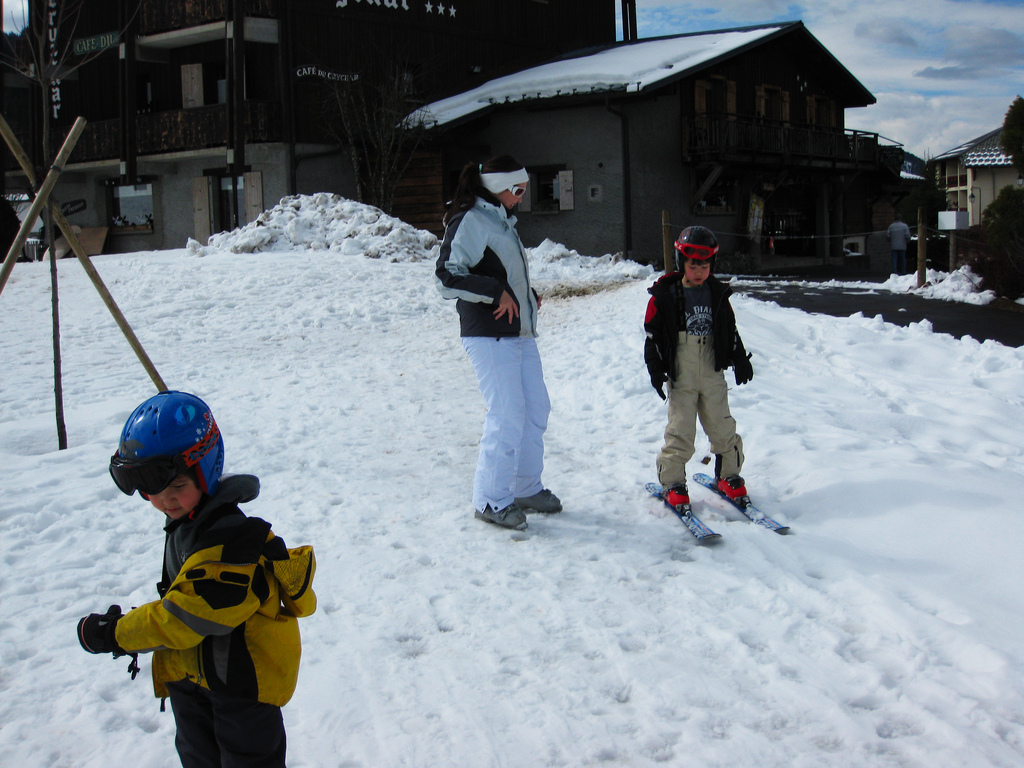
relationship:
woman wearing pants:
[450, 146, 568, 524] [450, 326, 568, 524]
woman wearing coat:
[425, 144, 566, 533] [432, 196, 540, 337]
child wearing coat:
[109, 506, 321, 716] [109, 506, 321, 716]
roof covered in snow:
[390, 17, 877, 125] [396, 22, 783, 133]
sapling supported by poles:
[4, 1, 94, 455] [2, 109, 170, 454]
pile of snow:
[177, 187, 435, 261] [269, 144, 341, 281]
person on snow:
[438, 149, 565, 538] [7, 149, 1023, 764]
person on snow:
[71, 351, 337, 754] [7, 149, 1023, 764]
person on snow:
[639, 217, 753, 503] [7, 149, 1023, 764]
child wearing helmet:
[73, 386, 317, 766] [105, 386, 224, 504]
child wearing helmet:
[629, 219, 757, 511] [664, 223, 725, 287]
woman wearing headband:
[425, 144, 566, 533] [475, 165, 534, 197]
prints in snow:
[2, 248, 1021, 764] [2, 20, 1021, 766]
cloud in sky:
[781, 8, 1019, 156] [2, 0, 1021, 163]